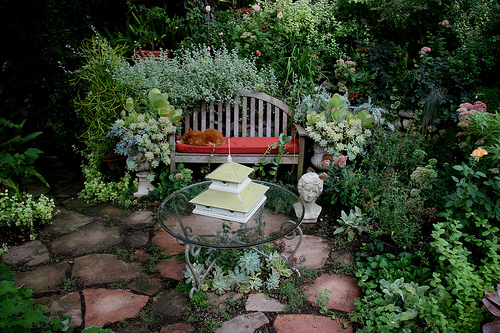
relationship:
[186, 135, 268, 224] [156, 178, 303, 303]
bird house on table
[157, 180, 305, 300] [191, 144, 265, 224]
rable with birdhouse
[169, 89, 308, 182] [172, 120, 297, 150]
bench with cushion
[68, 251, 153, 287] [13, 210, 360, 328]
stone used as walkway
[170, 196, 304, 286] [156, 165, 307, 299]
legs of table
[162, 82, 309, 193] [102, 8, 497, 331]
bench in garden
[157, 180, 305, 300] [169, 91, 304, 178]
rable in front bench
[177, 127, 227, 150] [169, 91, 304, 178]
animal lying on bench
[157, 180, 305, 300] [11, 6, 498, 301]
rable in garden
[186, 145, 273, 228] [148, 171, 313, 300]
decoration on table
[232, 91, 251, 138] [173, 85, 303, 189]
slat on bench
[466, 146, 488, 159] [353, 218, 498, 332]
flower on bush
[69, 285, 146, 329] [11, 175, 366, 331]
rock stuck on ground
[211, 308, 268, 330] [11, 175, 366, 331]
rock stuck on ground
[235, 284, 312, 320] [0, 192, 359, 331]
rock stuck on ground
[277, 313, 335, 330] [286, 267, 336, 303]
rock stuck on ground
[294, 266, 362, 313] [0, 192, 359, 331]
rock stuck on ground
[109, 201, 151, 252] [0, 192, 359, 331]
rock stuck on ground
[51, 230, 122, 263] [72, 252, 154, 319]
rock stuck on ground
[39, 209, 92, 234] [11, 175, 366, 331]
rock stuck on ground